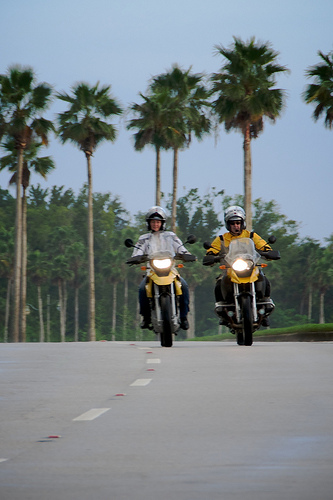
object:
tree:
[206, 32, 290, 228]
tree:
[125, 58, 213, 228]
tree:
[121, 93, 168, 203]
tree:
[1, 61, 59, 341]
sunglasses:
[227, 220, 243, 226]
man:
[203, 204, 270, 332]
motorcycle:
[198, 243, 282, 349]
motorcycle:
[125, 248, 198, 349]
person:
[127, 202, 196, 329]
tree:
[54, 74, 126, 342]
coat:
[199, 223, 278, 288]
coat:
[206, 226, 273, 282]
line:
[69, 404, 108, 420]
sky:
[1, 1, 331, 249]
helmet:
[146, 206, 169, 231]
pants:
[137, 271, 191, 334]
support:
[250, 280, 258, 326]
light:
[231, 257, 251, 275]